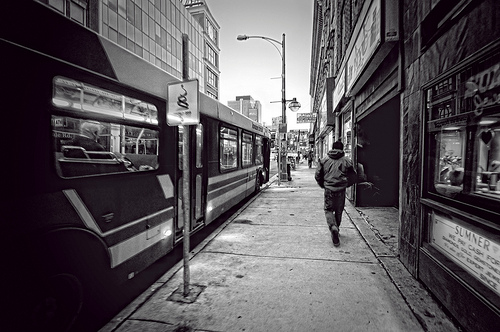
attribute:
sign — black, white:
[174, 84, 191, 113]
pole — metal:
[177, 126, 194, 298]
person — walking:
[314, 141, 358, 252]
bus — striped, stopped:
[13, 78, 275, 315]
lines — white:
[108, 166, 284, 262]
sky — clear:
[223, 10, 305, 97]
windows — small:
[427, 120, 500, 196]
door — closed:
[176, 107, 207, 243]